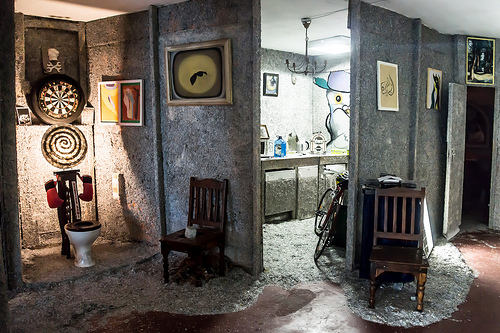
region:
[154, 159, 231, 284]
Chair against the wall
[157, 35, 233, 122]
Picture on the wall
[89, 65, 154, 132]
Picture on the wall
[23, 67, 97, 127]
Dart board on the wall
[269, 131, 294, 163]
Bottle on the counter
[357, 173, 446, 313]
Brown wooden chair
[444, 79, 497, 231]
Open door to dark room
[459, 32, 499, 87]
Picture over the door way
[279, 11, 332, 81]
Light hanging from the ceiling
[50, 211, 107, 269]
Toilet bowl in the corner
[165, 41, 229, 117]
brown frame on picture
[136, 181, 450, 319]
two dark brown chairs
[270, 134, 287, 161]
blue bottle in distance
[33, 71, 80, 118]
dartboard is on wall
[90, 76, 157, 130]
red and yellow picture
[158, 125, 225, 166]
wall is stone grey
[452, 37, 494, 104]
picture is above door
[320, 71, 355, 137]
drawing is on wall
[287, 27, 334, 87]
brown chandelier in kitchen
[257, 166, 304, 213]
grey door on dishwasher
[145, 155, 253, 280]
this is a chair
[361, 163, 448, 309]
this is a chair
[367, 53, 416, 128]
this is a picture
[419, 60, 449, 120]
this is a picture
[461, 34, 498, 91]
this is a picture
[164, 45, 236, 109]
this is a picture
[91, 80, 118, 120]
this is a picture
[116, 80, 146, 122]
this is a picture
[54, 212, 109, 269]
this is a toilet bowl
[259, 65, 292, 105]
this is a picture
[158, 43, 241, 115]
picture in a frame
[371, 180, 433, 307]
wooden chair on the floor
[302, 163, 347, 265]
mountain bike in the room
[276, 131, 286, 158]
bottle of liquid on a table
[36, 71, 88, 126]
dart board on the wall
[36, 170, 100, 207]
boxing gloves on the shelf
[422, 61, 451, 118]
picture on the wall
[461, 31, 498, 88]
picture on the wall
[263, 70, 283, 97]
picture on the wall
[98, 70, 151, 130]
picture on the wall